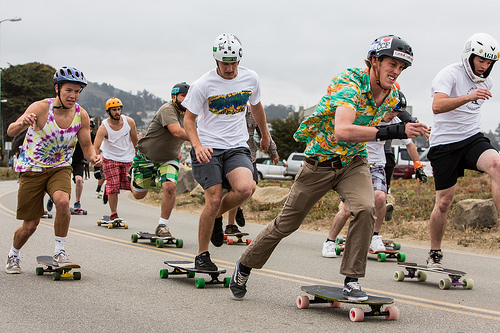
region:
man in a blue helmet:
[52, 63, 89, 108]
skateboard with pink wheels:
[290, 278, 400, 323]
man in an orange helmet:
[103, 96, 124, 121]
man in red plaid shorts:
[98, 157, 131, 197]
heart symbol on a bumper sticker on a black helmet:
[381, 35, 390, 42]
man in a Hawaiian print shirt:
[290, 33, 407, 163]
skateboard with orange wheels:
[218, 229, 254, 246]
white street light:
[0, 10, 27, 32]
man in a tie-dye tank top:
[13, 96, 90, 181]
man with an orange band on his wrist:
[412, 160, 422, 169]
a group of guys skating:
[21, 20, 491, 318]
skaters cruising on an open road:
[20, 10, 497, 325]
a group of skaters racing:
[5, 30, 495, 320]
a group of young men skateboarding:
[15, 25, 495, 310]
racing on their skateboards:
[22, 27, 494, 327]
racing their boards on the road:
[20, 21, 495, 316]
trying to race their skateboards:
[25, 35, 495, 327]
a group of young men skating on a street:
[26, 26, 496, 321]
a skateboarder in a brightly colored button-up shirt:
[291, 22, 424, 302]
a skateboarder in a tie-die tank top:
[13, 55, 119, 327]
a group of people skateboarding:
[0, 32, 499, 330]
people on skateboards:
[2, 41, 499, 321]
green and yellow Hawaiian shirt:
[291, 62, 408, 164]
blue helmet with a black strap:
[48, 61, 101, 123]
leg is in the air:
[212, 171, 259, 251]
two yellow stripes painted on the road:
[18, 203, 493, 329]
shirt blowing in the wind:
[286, 105, 331, 159]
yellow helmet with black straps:
[98, 89, 128, 128]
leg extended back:
[223, 181, 322, 309]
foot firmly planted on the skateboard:
[189, 244, 224, 278]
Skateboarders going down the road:
[104, 23, 411, 269]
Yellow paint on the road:
[417, 280, 490, 321]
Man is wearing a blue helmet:
[41, 52, 88, 104]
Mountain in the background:
[70, 70, 169, 118]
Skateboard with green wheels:
[162, 246, 234, 307]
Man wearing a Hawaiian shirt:
[316, 57, 400, 174]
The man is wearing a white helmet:
[177, 18, 255, 86]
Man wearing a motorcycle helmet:
[437, 10, 498, 91]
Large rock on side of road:
[437, 195, 495, 234]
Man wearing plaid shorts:
[102, 152, 132, 214]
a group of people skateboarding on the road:
[14, 5, 491, 277]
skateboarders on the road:
[23, 1, 497, 297]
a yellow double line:
[7, 128, 499, 325]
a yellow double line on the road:
[4, 111, 471, 331]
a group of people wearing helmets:
[22, 8, 495, 233]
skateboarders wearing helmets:
[5, 11, 465, 300]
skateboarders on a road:
[17, 27, 490, 247]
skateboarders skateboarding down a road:
[19, 13, 486, 332]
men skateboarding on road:
[9, 8, 493, 250]